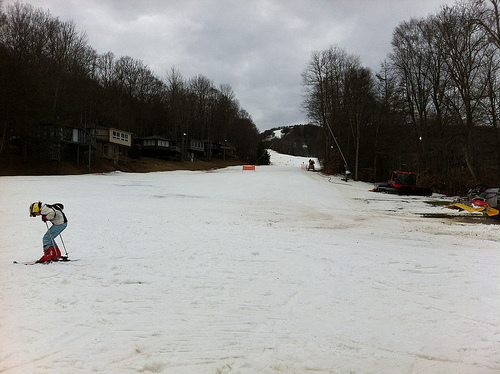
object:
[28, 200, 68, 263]
person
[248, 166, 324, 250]
ground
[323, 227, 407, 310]
snow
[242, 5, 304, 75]
sky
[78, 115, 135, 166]
house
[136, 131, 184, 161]
house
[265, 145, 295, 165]
slope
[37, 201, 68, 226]
ski jacket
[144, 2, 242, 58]
sky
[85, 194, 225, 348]
snow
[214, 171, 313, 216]
snow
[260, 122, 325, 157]
hill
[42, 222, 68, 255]
pants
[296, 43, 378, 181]
trees